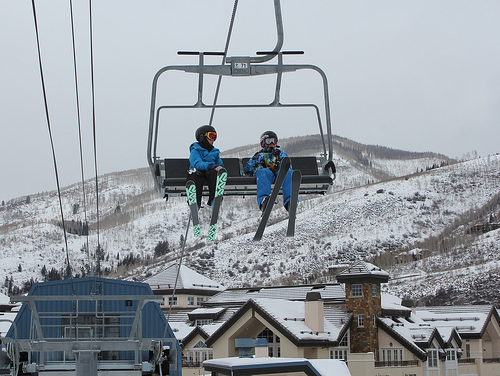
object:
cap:
[195, 125, 217, 142]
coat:
[189, 141, 226, 172]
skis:
[206, 168, 228, 241]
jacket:
[242, 147, 293, 177]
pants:
[256, 168, 300, 209]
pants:
[186, 170, 226, 209]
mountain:
[0, 134, 500, 308]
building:
[0, 261, 500, 375]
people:
[186, 125, 227, 211]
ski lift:
[147, 50, 336, 197]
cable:
[40, 3, 103, 297]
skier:
[185, 125, 229, 242]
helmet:
[260, 131, 278, 148]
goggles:
[205, 132, 217, 141]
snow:
[0, 134, 499, 306]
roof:
[249, 297, 347, 342]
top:
[218, 133, 450, 160]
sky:
[0, 0, 499, 202]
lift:
[0, 296, 177, 375]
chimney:
[335, 260, 388, 362]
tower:
[346, 281, 381, 354]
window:
[358, 314, 365, 328]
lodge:
[142, 259, 500, 375]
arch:
[228, 315, 281, 360]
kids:
[240, 131, 300, 212]